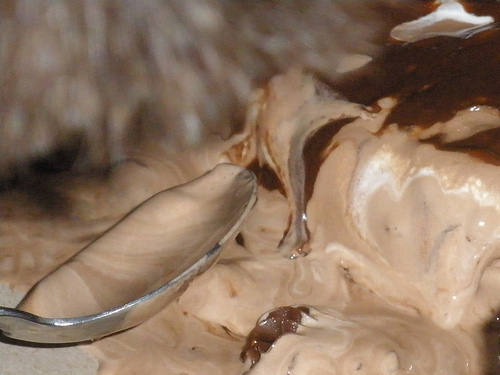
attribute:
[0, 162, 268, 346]
spoon — metallic, oval, silver, metal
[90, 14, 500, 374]
cream — pink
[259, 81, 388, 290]
down — dripping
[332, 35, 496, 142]
chocolate — brown, melting, melted, dark chocolate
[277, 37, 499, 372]
ice cream — brown, oozing, sweet, chocolate, melting, vanilla, swirled, melted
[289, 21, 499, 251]
syrup — hot, fudge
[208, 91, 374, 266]
chocolate — swirled